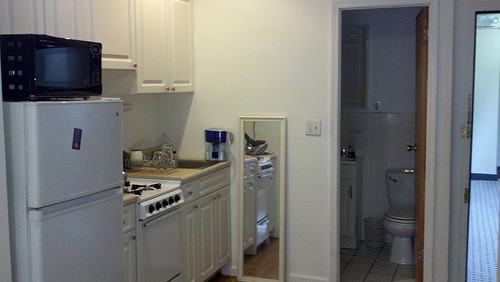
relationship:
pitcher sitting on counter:
[202, 127, 237, 162] [116, 151, 235, 184]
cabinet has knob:
[341, 162, 365, 252] [349, 182, 354, 203]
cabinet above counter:
[131, 0, 195, 96] [116, 151, 235, 184]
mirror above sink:
[340, 24, 374, 112] [337, 143, 364, 165]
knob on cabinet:
[349, 182, 354, 203] [341, 162, 365, 252]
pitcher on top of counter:
[202, 127, 237, 162] [116, 151, 235, 184]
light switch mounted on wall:
[306, 117, 322, 136] [154, 1, 341, 282]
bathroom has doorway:
[337, 2, 431, 281] [326, 3, 439, 281]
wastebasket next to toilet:
[361, 217, 385, 250] [379, 166, 420, 268]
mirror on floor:
[235, 113, 292, 281] [209, 271, 237, 281]